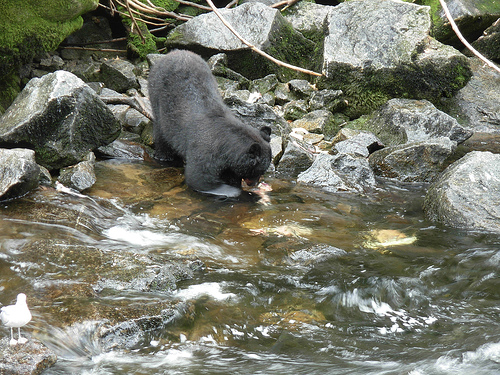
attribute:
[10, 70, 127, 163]
rock — here, gray, grey, large, wet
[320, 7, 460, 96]
rock — here, wet, gray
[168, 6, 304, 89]
rock — here, wet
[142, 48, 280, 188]
bear — black, big, wet, fishing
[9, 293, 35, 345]
bird — white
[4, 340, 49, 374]
stone — gray, wet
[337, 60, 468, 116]
moss — green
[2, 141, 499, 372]
water — rushing, here, moving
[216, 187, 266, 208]
paws — wet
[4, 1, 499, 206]
rocks — large